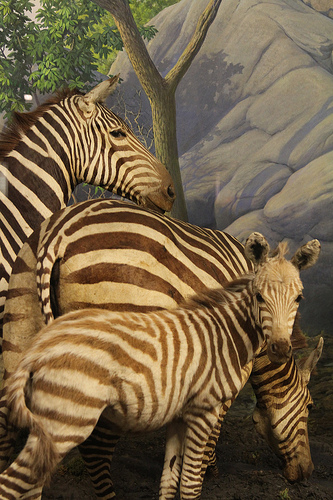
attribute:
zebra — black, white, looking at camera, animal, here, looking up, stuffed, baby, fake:
[9, 232, 319, 498]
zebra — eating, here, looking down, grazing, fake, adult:
[24, 217, 328, 477]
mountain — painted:
[97, 0, 328, 288]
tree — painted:
[5, 2, 227, 221]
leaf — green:
[83, 12, 94, 20]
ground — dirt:
[5, 451, 330, 494]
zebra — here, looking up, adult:
[2, 79, 171, 294]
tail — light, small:
[10, 342, 64, 473]